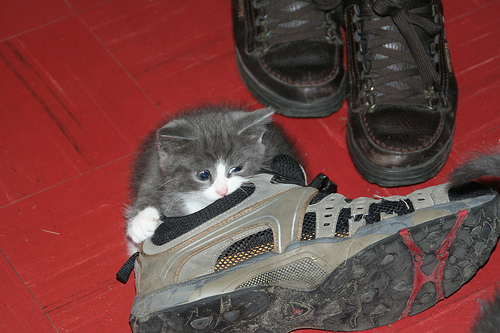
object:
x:
[397, 209, 465, 318]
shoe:
[128, 172, 496, 331]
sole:
[128, 194, 498, 332]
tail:
[444, 148, 499, 185]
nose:
[214, 185, 228, 196]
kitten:
[125, 102, 307, 257]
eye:
[192, 164, 214, 184]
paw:
[129, 207, 159, 242]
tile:
[2, 1, 499, 332]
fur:
[219, 185, 227, 190]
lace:
[355, 0, 446, 107]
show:
[230, 0, 347, 117]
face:
[176, 140, 260, 198]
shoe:
[345, 0, 459, 186]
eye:
[225, 159, 250, 179]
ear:
[157, 120, 203, 140]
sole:
[234, 41, 347, 117]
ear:
[234, 110, 280, 136]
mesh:
[214, 224, 275, 270]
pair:
[230, 0, 458, 186]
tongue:
[271, 154, 307, 185]